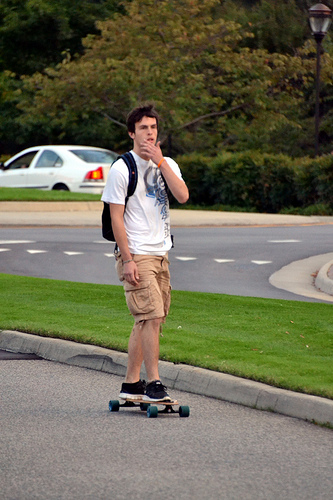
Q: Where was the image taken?
A: It was taken at the road.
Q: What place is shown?
A: It is a road.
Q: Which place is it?
A: It is a road.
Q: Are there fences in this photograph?
A: No, there are no fences.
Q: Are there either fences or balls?
A: No, there are no fences or balls.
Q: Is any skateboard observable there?
A: Yes, there is a skateboard.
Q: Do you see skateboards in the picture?
A: Yes, there is a skateboard.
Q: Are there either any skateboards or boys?
A: Yes, there is a skateboard.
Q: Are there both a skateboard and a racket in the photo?
A: No, there is a skateboard but no rackets.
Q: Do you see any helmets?
A: No, there are no helmets.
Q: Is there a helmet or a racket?
A: No, there are no helmets or rackets.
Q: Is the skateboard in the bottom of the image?
A: Yes, the skateboard is in the bottom of the image.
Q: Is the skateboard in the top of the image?
A: No, the skateboard is in the bottom of the image.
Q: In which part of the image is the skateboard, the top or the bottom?
A: The skateboard is in the bottom of the image.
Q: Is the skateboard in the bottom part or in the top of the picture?
A: The skateboard is in the bottom of the image.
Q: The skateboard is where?
A: The skateboard is on the road.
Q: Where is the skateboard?
A: The skateboard is on the road.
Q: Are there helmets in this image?
A: No, there are no helmets.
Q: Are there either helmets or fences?
A: No, there are no helmets or fences.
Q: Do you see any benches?
A: No, there are no benches.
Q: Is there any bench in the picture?
A: No, there are no benches.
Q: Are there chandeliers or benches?
A: No, there are no benches or chandeliers.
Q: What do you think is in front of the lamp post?
A: The hedge is in front of the lamp post.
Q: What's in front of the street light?
A: The hedge is in front of the lamp post.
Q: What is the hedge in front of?
A: The hedge is in front of the street lamp.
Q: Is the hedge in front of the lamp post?
A: Yes, the hedge is in front of the lamp post.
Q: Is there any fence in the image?
A: No, there are no fences.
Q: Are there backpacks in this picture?
A: Yes, there is a backpack.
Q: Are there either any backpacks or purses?
A: Yes, there is a backpack.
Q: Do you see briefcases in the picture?
A: No, there are no briefcases.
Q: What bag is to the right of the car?
A: The bag is a backpack.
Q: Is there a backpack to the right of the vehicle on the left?
A: Yes, there is a backpack to the right of the car.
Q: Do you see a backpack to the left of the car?
A: No, the backpack is to the right of the car.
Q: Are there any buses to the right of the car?
A: No, there is a backpack to the right of the car.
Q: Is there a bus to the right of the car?
A: No, there is a backpack to the right of the car.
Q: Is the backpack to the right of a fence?
A: No, the backpack is to the right of the car.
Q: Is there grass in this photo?
A: Yes, there is grass.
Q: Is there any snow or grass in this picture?
A: Yes, there is grass.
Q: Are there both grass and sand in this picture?
A: No, there is grass but no sand.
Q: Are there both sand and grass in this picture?
A: No, there is grass but no sand.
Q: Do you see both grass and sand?
A: No, there is grass but no sand.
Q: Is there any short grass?
A: Yes, there is short grass.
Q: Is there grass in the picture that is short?
A: Yes, there is grass that is short.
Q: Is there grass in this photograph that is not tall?
A: Yes, there is short grass.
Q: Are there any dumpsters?
A: No, there are no dumpsters.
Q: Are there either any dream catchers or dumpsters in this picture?
A: No, there are no dumpsters or dream catchers.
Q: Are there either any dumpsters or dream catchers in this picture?
A: No, there are no dumpsters or dream catchers.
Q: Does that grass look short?
A: Yes, the grass is short.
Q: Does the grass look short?
A: Yes, the grass is short.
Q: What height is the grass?
A: The grass is short.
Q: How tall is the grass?
A: The grass is short.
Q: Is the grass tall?
A: No, the grass is short.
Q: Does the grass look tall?
A: No, the grass is short.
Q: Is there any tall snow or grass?
A: No, there is grass but it is short.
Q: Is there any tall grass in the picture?
A: No, there is grass but it is short.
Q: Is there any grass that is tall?
A: No, there is grass but it is short.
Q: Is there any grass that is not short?
A: No, there is grass but it is short.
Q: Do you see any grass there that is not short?
A: No, there is grass but it is short.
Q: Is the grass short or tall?
A: The grass is short.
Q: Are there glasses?
A: No, there are no glasses.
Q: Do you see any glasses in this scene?
A: No, there are no glasses.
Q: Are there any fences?
A: No, there are no fences.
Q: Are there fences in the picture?
A: No, there are no fences.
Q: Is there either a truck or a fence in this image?
A: No, there are no fences or trucks.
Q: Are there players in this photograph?
A: No, there are no players.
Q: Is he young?
A: Yes, the boy is young.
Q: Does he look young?
A: Yes, the boy is young.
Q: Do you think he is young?
A: Yes, the boy is young.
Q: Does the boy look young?
A: Yes, the boy is young.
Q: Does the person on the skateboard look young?
A: Yes, the boy is young.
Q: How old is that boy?
A: The boy is young.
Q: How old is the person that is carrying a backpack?
A: The boy is young.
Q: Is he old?
A: No, the boy is young.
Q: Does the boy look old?
A: No, the boy is young.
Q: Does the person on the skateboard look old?
A: No, the boy is young.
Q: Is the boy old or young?
A: The boy is young.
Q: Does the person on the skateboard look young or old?
A: The boy is young.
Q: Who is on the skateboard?
A: The boy is on the skateboard.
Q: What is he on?
A: The boy is on the skateboard.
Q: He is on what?
A: The boy is on the skateboard.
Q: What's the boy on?
A: The boy is on the skateboard.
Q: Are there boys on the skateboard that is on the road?
A: Yes, there is a boy on the skateboard.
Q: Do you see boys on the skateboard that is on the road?
A: Yes, there is a boy on the skateboard.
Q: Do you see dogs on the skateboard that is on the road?
A: No, there is a boy on the skateboard.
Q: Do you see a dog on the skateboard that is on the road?
A: No, there is a boy on the skateboard.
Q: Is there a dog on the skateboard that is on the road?
A: No, there is a boy on the skateboard.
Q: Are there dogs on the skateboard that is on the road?
A: No, there is a boy on the skateboard.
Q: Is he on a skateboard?
A: Yes, the boy is on a skateboard.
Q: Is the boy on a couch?
A: No, the boy is on a skateboard.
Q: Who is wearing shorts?
A: The boy is wearing shorts.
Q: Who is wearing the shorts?
A: The boy is wearing shorts.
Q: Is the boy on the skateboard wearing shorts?
A: Yes, the boy is wearing shorts.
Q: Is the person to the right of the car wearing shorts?
A: Yes, the boy is wearing shorts.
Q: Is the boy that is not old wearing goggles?
A: No, the boy is wearing shorts.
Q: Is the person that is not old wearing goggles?
A: No, the boy is wearing shorts.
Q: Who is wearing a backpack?
A: The boy is wearing a backpack.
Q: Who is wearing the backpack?
A: The boy is wearing a backpack.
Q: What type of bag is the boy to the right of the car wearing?
A: The boy is wearing a backpack.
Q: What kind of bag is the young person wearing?
A: The boy is wearing a backpack.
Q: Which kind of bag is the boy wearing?
A: The boy is wearing a backpack.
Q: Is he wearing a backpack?
A: Yes, the boy is wearing a backpack.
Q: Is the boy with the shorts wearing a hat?
A: No, the boy is wearing a backpack.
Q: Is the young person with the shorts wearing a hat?
A: No, the boy is wearing a backpack.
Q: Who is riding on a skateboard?
A: The boy is riding on a skateboard.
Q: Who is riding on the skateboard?
A: The boy is riding on a skateboard.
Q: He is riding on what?
A: The boy is riding on a skateboard.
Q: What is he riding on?
A: The boy is riding on a skateboard.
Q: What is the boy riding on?
A: The boy is riding on a skateboard.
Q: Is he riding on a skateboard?
A: Yes, the boy is riding on a skateboard.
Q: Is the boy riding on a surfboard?
A: No, the boy is riding on a skateboard.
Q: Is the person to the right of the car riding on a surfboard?
A: No, the boy is riding on a skateboard.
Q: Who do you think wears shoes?
A: The boy wears shoes.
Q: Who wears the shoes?
A: The boy wears shoes.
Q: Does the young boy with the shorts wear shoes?
A: Yes, the boy wears shoes.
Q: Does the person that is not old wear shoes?
A: Yes, the boy wears shoes.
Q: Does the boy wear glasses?
A: No, the boy wears shoes.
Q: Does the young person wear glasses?
A: No, the boy wears shoes.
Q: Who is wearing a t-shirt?
A: The boy is wearing a t-shirt.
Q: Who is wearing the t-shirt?
A: The boy is wearing a t-shirt.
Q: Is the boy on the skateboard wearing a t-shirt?
A: Yes, the boy is wearing a t-shirt.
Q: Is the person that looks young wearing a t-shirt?
A: Yes, the boy is wearing a t-shirt.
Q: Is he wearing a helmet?
A: No, the boy is wearing a t-shirt.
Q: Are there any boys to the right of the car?
A: Yes, there is a boy to the right of the car.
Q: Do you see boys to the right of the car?
A: Yes, there is a boy to the right of the car.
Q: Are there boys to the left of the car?
A: No, the boy is to the right of the car.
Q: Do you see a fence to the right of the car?
A: No, there is a boy to the right of the car.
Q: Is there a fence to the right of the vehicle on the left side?
A: No, there is a boy to the right of the car.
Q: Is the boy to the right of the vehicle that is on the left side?
A: Yes, the boy is to the right of the car.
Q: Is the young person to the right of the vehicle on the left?
A: Yes, the boy is to the right of the car.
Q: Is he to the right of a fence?
A: No, the boy is to the right of the car.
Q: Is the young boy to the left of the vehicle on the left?
A: No, the boy is to the right of the car.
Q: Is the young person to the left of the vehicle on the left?
A: No, the boy is to the right of the car.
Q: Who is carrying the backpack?
A: The boy is carrying the backpack.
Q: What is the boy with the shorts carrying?
A: The boy is carrying a backpack.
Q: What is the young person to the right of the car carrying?
A: The boy is carrying a backpack.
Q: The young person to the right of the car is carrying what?
A: The boy is carrying a backpack.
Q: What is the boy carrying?
A: The boy is carrying a backpack.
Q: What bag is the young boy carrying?
A: The boy is carrying a backpack.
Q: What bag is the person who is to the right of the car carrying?
A: The boy is carrying a backpack.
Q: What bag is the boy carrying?
A: The boy is carrying a backpack.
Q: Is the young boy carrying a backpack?
A: Yes, the boy is carrying a backpack.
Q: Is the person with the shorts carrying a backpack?
A: Yes, the boy is carrying a backpack.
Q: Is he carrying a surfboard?
A: No, the boy is carrying a backpack.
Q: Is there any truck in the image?
A: No, there are no trucks.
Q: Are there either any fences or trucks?
A: No, there are no trucks or fences.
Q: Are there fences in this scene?
A: No, there are no fences.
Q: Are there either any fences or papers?
A: No, there are no fences or papers.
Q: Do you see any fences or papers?
A: No, there are no fences or papers.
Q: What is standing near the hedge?
A: The lamp post is standing near the hedge.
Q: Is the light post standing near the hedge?
A: Yes, the light post is standing near the hedge.